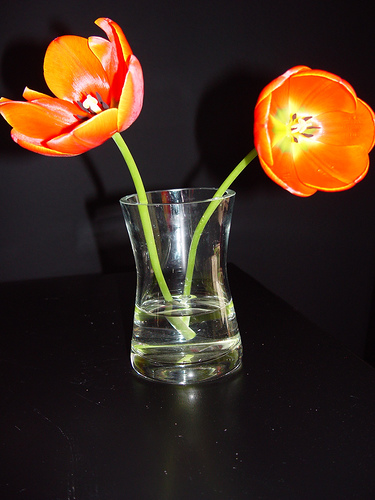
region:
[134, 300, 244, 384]
Water in clear vase.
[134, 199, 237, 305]
Green stems showing through vase.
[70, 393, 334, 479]
Black display case under vase.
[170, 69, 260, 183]
Shadow from healthy flower.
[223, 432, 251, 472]
White specs on black display.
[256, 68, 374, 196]
Orange tang flower with white in the middle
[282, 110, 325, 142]
Seeds in the middle of flower.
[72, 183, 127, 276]
Shadow of glass vase.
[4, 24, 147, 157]
Orange flowers pointed to the left.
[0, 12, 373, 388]
some sort of orange pink poppy, or poppylike flower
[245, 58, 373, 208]
six overlapping petals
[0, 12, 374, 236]
petals are thick, though, & not lacy in the way of many poppy petals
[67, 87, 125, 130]
still, in this case, in particular, the anther & stamen business are similar, if [only] visibly sparser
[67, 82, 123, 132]
the anther/stamen color, here, is very similar to the poppy stamen/anther combo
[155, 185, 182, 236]
a tiny orange flower reflection in a curvy clear glass glass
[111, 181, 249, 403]
a curvy clear glass glass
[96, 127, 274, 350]
two thick, green poppylike stems suspended in water, crossed @ the ends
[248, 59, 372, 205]
Orange flower in the forefront.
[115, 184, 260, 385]
clear vase on the table.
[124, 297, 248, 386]
Water in the vase.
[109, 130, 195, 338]
Green stem on the flower.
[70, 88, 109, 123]
Piston in the flower.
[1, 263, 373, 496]
Black table in the forefront.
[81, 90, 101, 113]
White color on the flower.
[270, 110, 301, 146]
Yellow color on the flower.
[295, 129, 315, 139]
Brown color on the flower.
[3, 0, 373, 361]
Dark grey color on the walls.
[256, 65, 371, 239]
the flower is orange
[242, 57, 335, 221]
the flower is orange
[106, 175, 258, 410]
water in the glass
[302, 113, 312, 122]
the stamen of a flower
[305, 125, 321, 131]
the stamen of a flower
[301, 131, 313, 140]
the stamen of a flower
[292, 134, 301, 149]
the stamen of a flower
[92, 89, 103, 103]
the stamen of a flower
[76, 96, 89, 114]
the stamen of a flower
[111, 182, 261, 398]
a glass vase with two flowers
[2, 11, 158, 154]
the bloom of a tulip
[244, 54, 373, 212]
the bloom of a tulip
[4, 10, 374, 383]
a vase of tulips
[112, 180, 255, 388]
small glass vase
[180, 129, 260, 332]
green flower stem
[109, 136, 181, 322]
green flower stem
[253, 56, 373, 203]
orange round flower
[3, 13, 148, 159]
orange round flower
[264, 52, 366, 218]
red and orange petals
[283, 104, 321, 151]
black and white anther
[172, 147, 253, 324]
long thin green stem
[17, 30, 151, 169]
red and orange petals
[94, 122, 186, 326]
long thin green stem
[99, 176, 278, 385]
circular wide mouthed cup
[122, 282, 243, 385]
water inside wide mouthed cup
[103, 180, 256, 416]
round thick glass vase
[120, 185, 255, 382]
glass vase with water in it